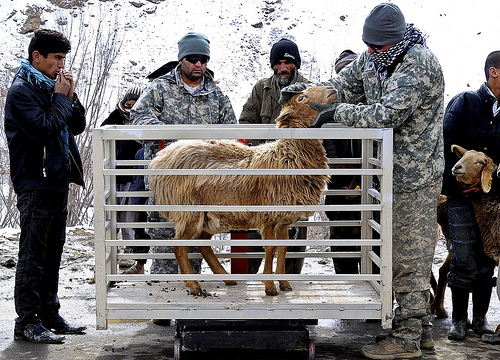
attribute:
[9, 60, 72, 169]
scarf — light blue, brown white, blac, blue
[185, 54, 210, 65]
sunglasses — dark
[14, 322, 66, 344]
shoe — black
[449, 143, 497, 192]
sheep — hairy, brown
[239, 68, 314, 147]
jacket — brown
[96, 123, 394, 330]
cage — white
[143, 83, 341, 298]
sheep — brown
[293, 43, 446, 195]
jacket — camo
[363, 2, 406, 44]
hat — gray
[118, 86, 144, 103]
hat — black, white